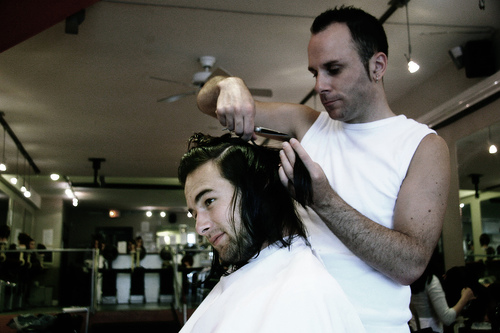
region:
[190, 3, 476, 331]
this is a man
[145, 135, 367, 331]
this is a man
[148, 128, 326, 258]
the man has black hair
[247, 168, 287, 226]
the man has black hair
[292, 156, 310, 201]
the man has black hair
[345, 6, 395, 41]
the man has black hair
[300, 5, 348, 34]
the man has black hair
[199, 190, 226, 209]
the eye of a man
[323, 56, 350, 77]
the eye of a man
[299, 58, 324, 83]
the eye of a man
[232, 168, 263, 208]
the hair is black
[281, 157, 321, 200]
the hair is black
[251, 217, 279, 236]
the hair is black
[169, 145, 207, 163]
the hair is black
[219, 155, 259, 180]
the hair is black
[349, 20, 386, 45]
the hair is black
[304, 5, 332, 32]
the hair is black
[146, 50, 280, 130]
this is a van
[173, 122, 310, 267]
guy with black hair getting a hair cut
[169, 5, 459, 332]
barber cutting a man's hair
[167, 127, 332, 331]
a guy has a white apron on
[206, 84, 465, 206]
man holding hair in hand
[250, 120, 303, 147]
comb in his hair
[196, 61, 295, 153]
comb in barbers hand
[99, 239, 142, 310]
white hair dryer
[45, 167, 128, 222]
lights on the ceiling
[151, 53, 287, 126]
light fan fixture on wall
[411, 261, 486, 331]
person in a white shirt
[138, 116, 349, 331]
man with black hair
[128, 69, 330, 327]
man getting his hair cut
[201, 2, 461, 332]
male hairdresser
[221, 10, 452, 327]
man in a white tank top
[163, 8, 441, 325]
two men in a hair salon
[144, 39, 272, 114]
white ceiling fan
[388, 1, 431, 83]
hanging ceiling light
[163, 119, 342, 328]
man in a white apron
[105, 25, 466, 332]
people in a hair salon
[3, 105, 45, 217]
hanging ceiling lights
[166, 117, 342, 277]
A man getting his hair cut.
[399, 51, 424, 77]
A very bright light bulb in the back ground.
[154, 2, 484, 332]
A man cutting another mans' hair.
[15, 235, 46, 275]
A lady sitting in a chair.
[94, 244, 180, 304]
Three hair driers in a row.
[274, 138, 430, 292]
A mans' hairy arm.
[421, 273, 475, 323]
A ladies' arm in the back ground.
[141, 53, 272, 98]
A fan is in the back ground.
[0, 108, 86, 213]
Light fixtures hanging from a ceiling.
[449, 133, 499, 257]
A mirror hanging on the wall.